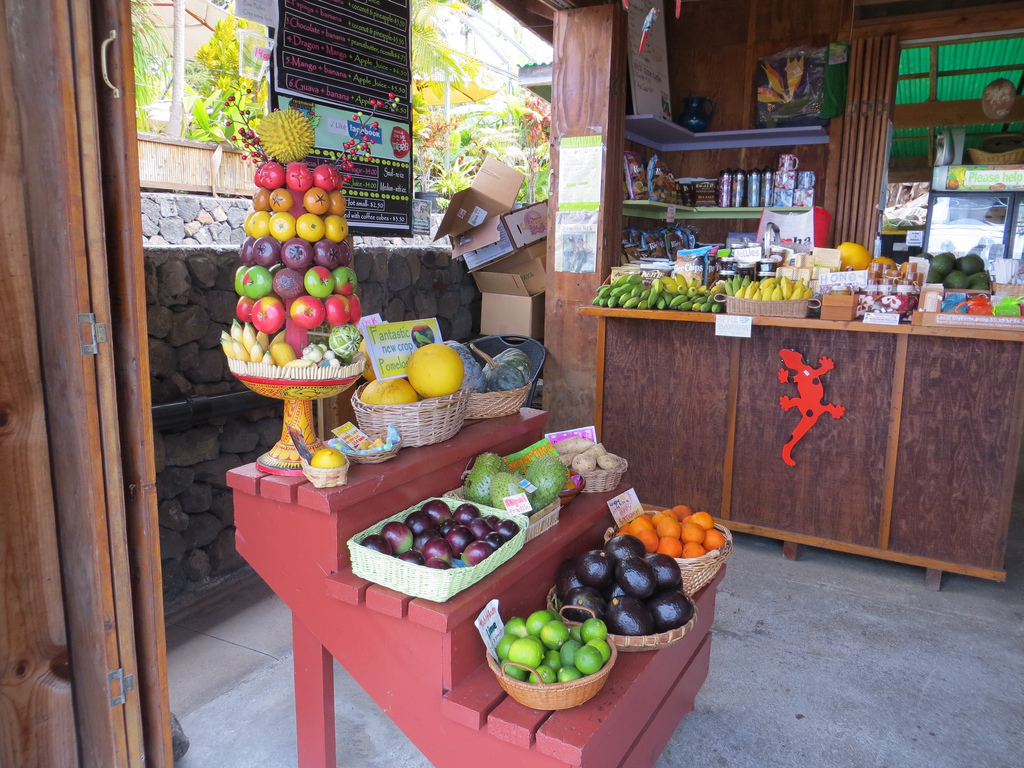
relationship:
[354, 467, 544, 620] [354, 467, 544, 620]
mangoes in basket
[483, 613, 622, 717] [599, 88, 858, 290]
fruit on shelf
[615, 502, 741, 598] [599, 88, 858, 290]
fruit on shelf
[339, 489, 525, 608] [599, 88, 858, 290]
fruit on shelf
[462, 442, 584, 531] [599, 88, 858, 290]
fruit on shelf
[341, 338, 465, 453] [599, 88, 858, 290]
fruit on shelf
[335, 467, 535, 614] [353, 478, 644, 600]
basket of fruit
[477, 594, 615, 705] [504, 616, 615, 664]
bowl of fruit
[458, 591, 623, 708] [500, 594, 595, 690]
basket of limes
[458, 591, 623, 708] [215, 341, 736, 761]
basket on display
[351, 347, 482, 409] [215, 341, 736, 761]
grapefruit on display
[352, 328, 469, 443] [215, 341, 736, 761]
basket on display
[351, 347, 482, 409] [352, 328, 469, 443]
grapefruit in basket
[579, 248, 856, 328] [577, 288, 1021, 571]
bananas on counter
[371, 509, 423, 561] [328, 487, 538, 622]
mangoes inside basket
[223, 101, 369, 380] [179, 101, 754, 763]
fruit tree on display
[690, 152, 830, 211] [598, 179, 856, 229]
cups on shelf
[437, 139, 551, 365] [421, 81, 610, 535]
boxes in corner